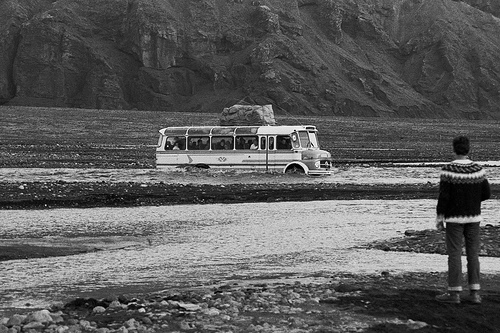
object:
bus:
[155, 124, 334, 176]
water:
[0, 160, 498, 187]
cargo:
[218, 98, 277, 126]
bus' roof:
[157, 125, 318, 134]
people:
[166, 136, 291, 151]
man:
[435, 135, 492, 305]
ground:
[1, 103, 500, 331]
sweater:
[436, 159, 492, 225]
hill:
[1, 1, 499, 123]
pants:
[444, 222, 483, 291]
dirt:
[332, 281, 497, 332]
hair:
[452, 135, 470, 156]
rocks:
[11, 179, 232, 202]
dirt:
[0, 173, 496, 208]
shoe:
[434, 290, 461, 304]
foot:
[431, 286, 463, 307]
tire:
[285, 163, 305, 178]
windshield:
[290, 129, 318, 150]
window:
[235, 135, 259, 150]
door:
[259, 134, 276, 170]